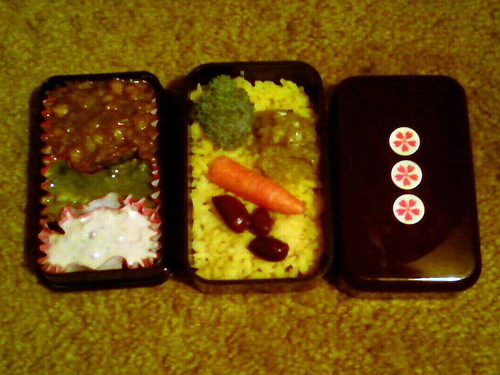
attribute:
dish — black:
[150, 33, 330, 280]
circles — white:
[387, 123, 426, 231]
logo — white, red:
[389, 126, 425, 225]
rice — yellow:
[191, 79, 318, 270]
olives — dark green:
[205, 185, 303, 274]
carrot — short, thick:
[207, 157, 306, 215]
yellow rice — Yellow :
[197, 224, 242, 271]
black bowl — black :
[35, 74, 390, 291]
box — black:
[300, 81, 460, 266]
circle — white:
[388, 125, 420, 155]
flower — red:
[391, 127, 418, 151]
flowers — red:
[395, 165, 420, 220]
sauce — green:
[47, 172, 154, 201]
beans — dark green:
[41, 82, 163, 192]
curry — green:
[199, 73, 258, 151]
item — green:
[200, 79, 256, 148]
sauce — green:
[63, 169, 150, 194]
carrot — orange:
[207, 154, 302, 213]